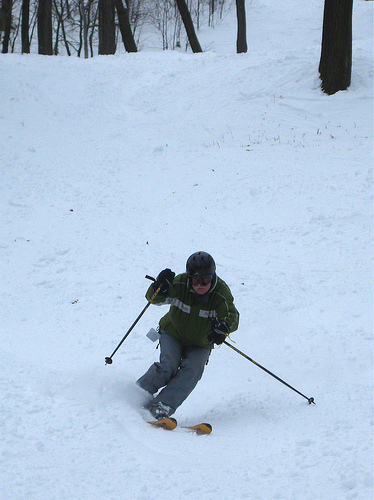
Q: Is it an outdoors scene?
A: Yes, it is outdoors.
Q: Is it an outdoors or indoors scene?
A: It is outdoors.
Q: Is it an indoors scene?
A: No, it is outdoors.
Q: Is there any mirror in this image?
A: No, there are no mirrors.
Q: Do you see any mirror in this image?
A: No, there are no mirrors.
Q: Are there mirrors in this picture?
A: No, there are no mirrors.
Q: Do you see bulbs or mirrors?
A: No, there are no mirrors or bulbs.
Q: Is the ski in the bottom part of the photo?
A: Yes, the ski is in the bottom of the image.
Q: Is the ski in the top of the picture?
A: No, the ski is in the bottom of the image.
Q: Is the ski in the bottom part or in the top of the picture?
A: The ski is in the bottom of the image.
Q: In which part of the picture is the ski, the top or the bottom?
A: The ski is in the bottom of the image.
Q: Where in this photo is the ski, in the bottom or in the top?
A: The ski is in the bottom of the image.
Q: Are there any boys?
A: No, there are no boys.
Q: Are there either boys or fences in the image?
A: No, there are no boys or fences.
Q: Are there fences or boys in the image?
A: No, there are no boys or fences.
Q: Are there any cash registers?
A: No, there are no cash registers.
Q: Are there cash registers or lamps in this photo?
A: No, there are no cash registers or lamps.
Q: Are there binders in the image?
A: No, there are no binders.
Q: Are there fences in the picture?
A: No, there are no fences.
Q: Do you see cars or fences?
A: No, there are no fences or cars.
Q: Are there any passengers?
A: No, there are no passengers.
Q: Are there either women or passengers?
A: No, there are no passengers or women.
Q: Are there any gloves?
A: Yes, there are gloves.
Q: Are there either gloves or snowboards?
A: Yes, there are gloves.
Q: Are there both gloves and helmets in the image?
A: Yes, there are both gloves and a helmet.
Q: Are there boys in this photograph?
A: No, there are no boys.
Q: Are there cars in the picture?
A: No, there are no cars.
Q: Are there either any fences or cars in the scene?
A: No, there are no cars or fences.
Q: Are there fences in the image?
A: No, there are no fences.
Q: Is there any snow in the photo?
A: Yes, there is snow.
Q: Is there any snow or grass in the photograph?
A: Yes, there is snow.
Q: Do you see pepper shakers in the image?
A: No, there are no pepper shakers.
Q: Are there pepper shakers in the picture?
A: No, there are no pepper shakers.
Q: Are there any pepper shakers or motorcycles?
A: No, there are no pepper shakers or motorcycles.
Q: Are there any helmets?
A: Yes, there is a helmet.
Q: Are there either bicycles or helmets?
A: Yes, there is a helmet.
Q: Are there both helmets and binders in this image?
A: No, there is a helmet but no binders.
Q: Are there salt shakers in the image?
A: No, there are no salt shakers.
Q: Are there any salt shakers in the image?
A: No, there are no salt shakers.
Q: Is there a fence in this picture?
A: No, there are no fences.